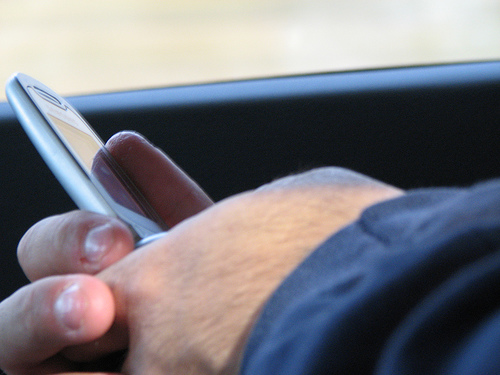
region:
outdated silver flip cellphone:
[0, 72, 154, 236]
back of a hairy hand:
[146, 257, 243, 340]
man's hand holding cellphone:
[9, 119, 234, 370]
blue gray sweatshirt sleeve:
[297, 180, 487, 372]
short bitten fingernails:
[68, 217, 120, 269]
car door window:
[134, 33, 486, 158]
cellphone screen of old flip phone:
[42, 113, 164, 223]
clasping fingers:
[21, 135, 201, 372]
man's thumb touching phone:
[96, 122, 211, 212]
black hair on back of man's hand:
[135, 290, 256, 371]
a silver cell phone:
[3, 70, 160, 236]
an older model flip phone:
[0, 87, 179, 237]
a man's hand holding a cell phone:
[8, 90, 448, 373]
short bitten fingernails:
[59, 220, 118, 350]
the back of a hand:
[83, 209, 316, 366]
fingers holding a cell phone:
[59, 103, 165, 253]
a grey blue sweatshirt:
[231, 168, 492, 368]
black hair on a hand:
[134, 216, 266, 361]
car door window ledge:
[104, 62, 495, 133]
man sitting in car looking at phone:
[66, 22, 491, 369]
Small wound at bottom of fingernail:
[64, 221, 136, 268]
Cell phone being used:
[10, 70, 162, 245]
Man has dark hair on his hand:
[115, 162, 366, 359]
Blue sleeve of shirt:
[250, 179, 498, 374]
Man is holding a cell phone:
[3, 65, 383, 374]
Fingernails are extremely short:
[38, 219, 131, 340]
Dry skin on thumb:
[106, 122, 152, 177]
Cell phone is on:
[11, 71, 166, 236]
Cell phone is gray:
[1, 70, 177, 250]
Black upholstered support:
[143, 61, 481, 156]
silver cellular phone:
[3, 67, 187, 259]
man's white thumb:
[99, 130, 231, 236]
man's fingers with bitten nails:
[4, 218, 149, 354]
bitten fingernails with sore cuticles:
[68, 208, 132, 270]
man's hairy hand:
[119, 155, 358, 341]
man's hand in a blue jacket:
[118, 169, 498, 364]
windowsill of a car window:
[108, 69, 408, 100]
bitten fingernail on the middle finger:
[43, 276, 108, 341]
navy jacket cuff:
[257, 276, 382, 346]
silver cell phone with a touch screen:
[2, 68, 177, 242]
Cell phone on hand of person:
[1, 70, 167, 251]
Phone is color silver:
[1, 67, 174, 255]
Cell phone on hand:
[3, 72, 353, 373]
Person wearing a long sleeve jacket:
[233, 166, 497, 373]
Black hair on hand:
[129, 177, 342, 351]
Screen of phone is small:
[42, 100, 157, 230]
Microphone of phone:
[24, 80, 74, 110]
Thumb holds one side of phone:
[103, 123, 206, 218]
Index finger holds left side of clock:
[13, 208, 140, 275]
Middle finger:
[0, 275, 127, 360]